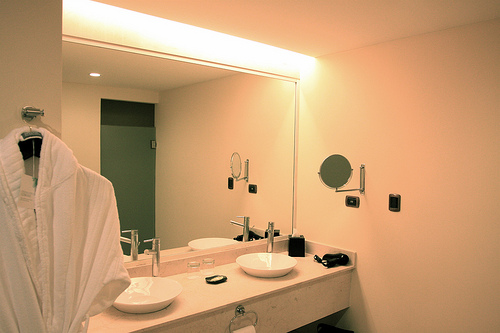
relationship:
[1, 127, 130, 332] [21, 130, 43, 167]
robe on a hanger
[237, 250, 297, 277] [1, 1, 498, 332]
double sinks in bathroom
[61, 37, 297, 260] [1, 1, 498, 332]
mirror mirror on wall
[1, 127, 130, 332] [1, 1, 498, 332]
white robe in bathroom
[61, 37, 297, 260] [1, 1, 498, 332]
mirror on wall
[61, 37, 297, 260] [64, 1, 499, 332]
mirror on wall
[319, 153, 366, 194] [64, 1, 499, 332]
mirror on wall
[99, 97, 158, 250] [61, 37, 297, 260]
green door reflection on mirror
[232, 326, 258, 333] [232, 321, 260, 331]
toilet paper in a roll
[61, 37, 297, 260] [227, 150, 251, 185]
mirror a magnifier mirror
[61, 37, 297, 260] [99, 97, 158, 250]
mirror of a door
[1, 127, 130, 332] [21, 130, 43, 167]
white bathrobe on hanger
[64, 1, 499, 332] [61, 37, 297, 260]
bathroom wall has a mirror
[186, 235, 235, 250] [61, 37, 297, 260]
white sink reflected on mirror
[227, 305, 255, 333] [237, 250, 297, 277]
toilet holder below sink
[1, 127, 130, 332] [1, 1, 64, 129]
bathrobe on wall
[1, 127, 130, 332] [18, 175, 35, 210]
bathrobe has a tag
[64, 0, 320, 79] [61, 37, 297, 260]
fluorescent light above mirror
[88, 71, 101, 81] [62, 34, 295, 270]
light imaged in mirror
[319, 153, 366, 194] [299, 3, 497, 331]
mirror attached to wall